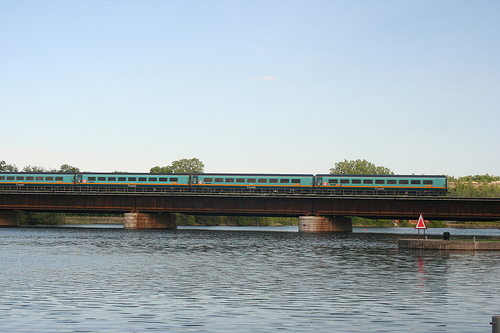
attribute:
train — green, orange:
[1, 171, 447, 194]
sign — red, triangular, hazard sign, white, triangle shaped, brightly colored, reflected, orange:
[415, 212, 428, 229]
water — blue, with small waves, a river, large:
[0, 223, 499, 333]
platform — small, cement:
[397, 237, 499, 253]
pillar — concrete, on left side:
[123, 212, 178, 231]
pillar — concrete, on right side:
[298, 216, 354, 234]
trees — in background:
[1, 161, 82, 173]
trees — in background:
[150, 158, 204, 175]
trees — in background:
[329, 158, 395, 177]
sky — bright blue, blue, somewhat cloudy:
[1, 0, 499, 179]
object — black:
[443, 231, 452, 242]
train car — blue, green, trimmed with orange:
[1, 172, 77, 188]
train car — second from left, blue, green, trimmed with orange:
[80, 172, 191, 186]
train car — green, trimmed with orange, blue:
[192, 174, 314, 189]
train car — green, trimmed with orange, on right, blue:
[317, 176, 448, 191]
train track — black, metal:
[1, 194, 500, 220]